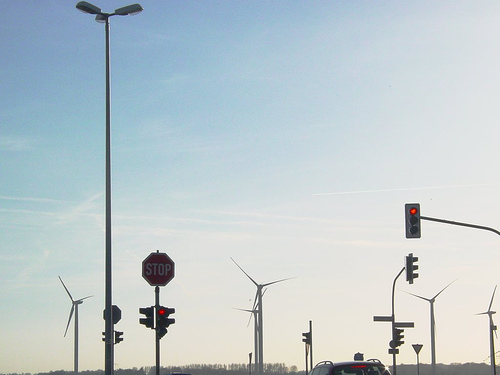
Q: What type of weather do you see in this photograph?
A: It is clear.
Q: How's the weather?
A: It is clear.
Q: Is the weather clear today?
A: Yes, it is clear.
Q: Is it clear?
A: Yes, it is clear.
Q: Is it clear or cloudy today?
A: It is clear.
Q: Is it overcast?
A: No, it is clear.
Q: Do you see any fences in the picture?
A: No, there are no fences.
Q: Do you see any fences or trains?
A: No, there are no fences or trains.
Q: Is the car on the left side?
A: No, the car is on the right of the image.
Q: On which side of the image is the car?
A: The car is on the right of the image.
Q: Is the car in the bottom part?
A: Yes, the car is in the bottom of the image.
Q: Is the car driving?
A: Yes, the car is driving.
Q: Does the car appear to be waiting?
A: No, the car is driving.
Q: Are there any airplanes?
A: No, there are no airplanes.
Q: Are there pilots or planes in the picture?
A: No, there are no planes or pilots.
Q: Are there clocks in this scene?
A: No, there are no clocks.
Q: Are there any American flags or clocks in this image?
A: No, there are no clocks or American flags.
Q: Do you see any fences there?
A: No, there are no fences.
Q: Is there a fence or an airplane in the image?
A: No, there are no fences or airplanes.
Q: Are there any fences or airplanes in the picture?
A: No, there are no fences or airplanes.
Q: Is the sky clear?
A: Yes, the sky is clear.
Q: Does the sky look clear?
A: Yes, the sky is clear.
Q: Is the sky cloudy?
A: No, the sky is clear.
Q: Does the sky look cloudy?
A: No, the sky is clear.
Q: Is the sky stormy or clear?
A: The sky is clear.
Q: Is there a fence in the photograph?
A: No, there are no fences.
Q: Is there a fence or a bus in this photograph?
A: No, there are no fences or buses.